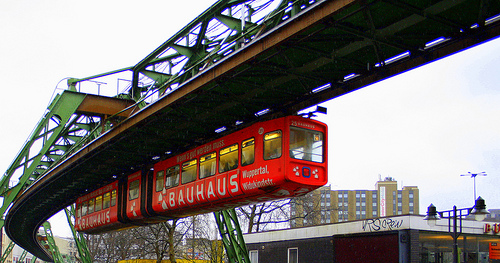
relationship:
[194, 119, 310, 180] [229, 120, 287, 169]
passenger in window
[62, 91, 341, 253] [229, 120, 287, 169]
train on window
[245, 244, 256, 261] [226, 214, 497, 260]
window on building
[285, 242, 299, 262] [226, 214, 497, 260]
window on building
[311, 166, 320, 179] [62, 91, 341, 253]
light on front of train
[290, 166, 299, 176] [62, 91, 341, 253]
light on front of train